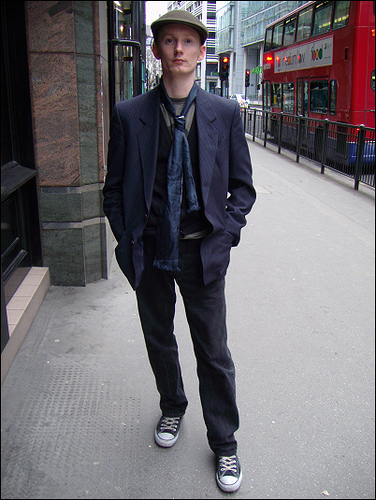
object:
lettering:
[272, 37, 333, 73]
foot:
[154, 398, 188, 449]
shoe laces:
[217, 455, 237, 474]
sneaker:
[213, 452, 242, 493]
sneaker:
[152, 412, 183, 447]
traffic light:
[244, 69, 249, 86]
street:
[241, 112, 374, 187]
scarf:
[153, 82, 206, 270]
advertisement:
[270, 40, 330, 75]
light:
[221, 55, 229, 65]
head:
[150, 8, 209, 78]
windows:
[331, 0, 348, 30]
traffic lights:
[216, 52, 229, 80]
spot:
[318, 488, 331, 500]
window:
[325, 79, 337, 114]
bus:
[260, 1, 374, 174]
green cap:
[147, 10, 208, 42]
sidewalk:
[0, 135, 375, 499]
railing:
[239, 106, 375, 194]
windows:
[309, 81, 327, 116]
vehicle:
[227, 94, 251, 110]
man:
[101, 8, 260, 496]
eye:
[163, 36, 174, 46]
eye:
[183, 36, 193, 44]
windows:
[214, 6, 232, 33]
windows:
[262, 26, 273, 53]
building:
[214, 1, 308, 107]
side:
[28, 1, 116, 288]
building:
[1, 2, 147, 384]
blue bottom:
[262, 120, 376, 176]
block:
[29, 52, 80, 188]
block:
[29, 2, 75, 51]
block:
[38, 190, 83, 225]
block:
[41, 229, 86, 286]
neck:
[161, 73, 195, 103]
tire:
[313, 129, 325, 161]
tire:
[270, 118, 280, 141]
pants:
[132, 234, 239, 456]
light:
[265, 52, 271, 61]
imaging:
[272, 38, 334, 76]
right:
[153, 415, 180, 447]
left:
[217, 453, 244, 493]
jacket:
[100, 82, 257, 293]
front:
[129, 102, 235, 282]